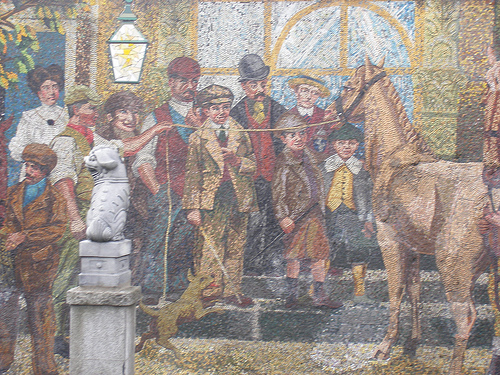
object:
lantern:
[104, 23, 149, 84]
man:
[95, 91, 147, 287]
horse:
[320, 52, 498, 374]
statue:
[64, 141, 145, 374]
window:
[196, 2, 263, 67]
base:
[64, 238, 142, 374]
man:
[127, 55, 207, 305]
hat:
[165, 55, 202, 80]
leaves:
[55, 19, 66, 36]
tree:
[0, 2, 25, 42]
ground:
[134, 336, 499, 374]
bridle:
[335, 90, 362, 123]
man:
[0, 142, 70, 374]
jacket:
[0, 178, 69, 295]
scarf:
[22, 177, 48, 208]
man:
[44, 84, 176, 360]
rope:
[169, 122, 344, 134]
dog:
[135, 266, 234, 356]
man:
[227, 53, 292, 277]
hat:
[235, 53, 270, 82]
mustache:
[253, 92, 266, 99]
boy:
[269, 114, 332, 304]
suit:
[269, 145, 334, 262]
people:
[7, 62, 71, 184]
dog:
[80, 141, 131, 245]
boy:
[320, 123, 378, 308]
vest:
[323, 163, 357, 213]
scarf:
[65, 123, 95, 146]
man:
[272, 71, 335, 164]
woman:
[6, 62, 71, 184]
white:
[7, 101, 70, 184]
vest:
[152, 103, 189, 199]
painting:
[1, 1, 499, 371]